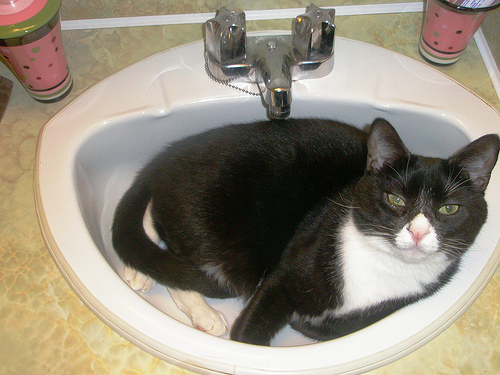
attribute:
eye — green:
[377, 185, 410, 214]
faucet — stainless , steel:
[194, 1, 344, 127]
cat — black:
[113, 107, 492, 287]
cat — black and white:
[105, 108, 499, 350]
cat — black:
[344, 117, 485, 279]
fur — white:
[324, 234, 389, 309]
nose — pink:
[410, 216, 427, 246]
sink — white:
[61, 11, 495, 374]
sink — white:
[125, 61, 485, 303]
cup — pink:
[1, 0, 73, 107]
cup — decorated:
[410, 1, 498, 63]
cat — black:
[113, 119, 474, 329]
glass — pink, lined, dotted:
[420, 0, 490, 72]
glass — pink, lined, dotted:
[4, 21, 86, 106]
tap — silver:
[182, 4, 351, 130]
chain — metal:
[224, 69, 262, 106]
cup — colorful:
[0, 0, 81, 106]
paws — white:
[166, 269, 267, 343]